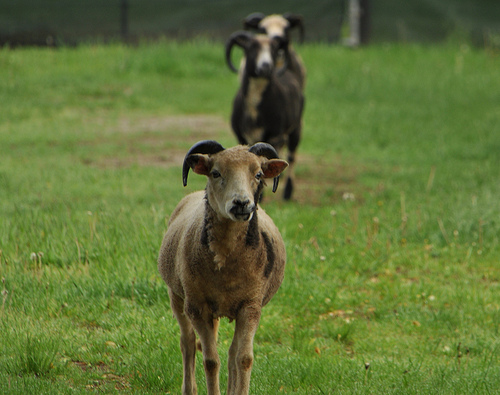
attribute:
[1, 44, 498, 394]
field — green, grassy 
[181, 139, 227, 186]
horn — long 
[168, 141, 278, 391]
goat — brown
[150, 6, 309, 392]
three rams — 3 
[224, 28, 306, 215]
ram — black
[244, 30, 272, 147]
marking — white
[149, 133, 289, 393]
ram — brown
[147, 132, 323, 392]
brown ram —  brown  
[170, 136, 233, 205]
horn — black curved 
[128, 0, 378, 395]
rams —  three 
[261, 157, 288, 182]
ears — brown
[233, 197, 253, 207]
nose — dark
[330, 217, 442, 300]
flower — some kind, blooming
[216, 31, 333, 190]
goats — grazing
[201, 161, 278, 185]
eyes — dark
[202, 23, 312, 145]
goats — black , white , brown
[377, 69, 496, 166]
grass — fairly long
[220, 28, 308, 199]
ram — 2 black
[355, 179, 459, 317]
grass — green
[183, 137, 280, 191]
horns — black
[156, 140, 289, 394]
brown ram — brown 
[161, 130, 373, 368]
ram — brown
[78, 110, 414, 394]
sheep — brown 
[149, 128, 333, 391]
horns — black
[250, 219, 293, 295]
marking — black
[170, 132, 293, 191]
horns — black curved 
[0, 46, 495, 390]
flowers — wild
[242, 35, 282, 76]
face — white